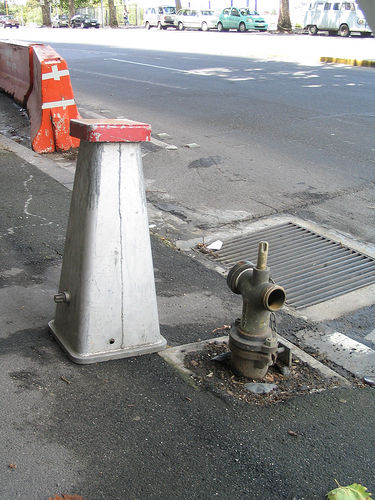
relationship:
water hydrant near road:
[226, 234, 294, 382] [2, 24, 375, 350]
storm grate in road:
[197, 222, 374, 307] [2, 24, 375, 350]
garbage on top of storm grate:
[198, 235, 229, 257] [197, 222, 374, 307]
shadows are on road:
[188, 57, 365, 93] [2, 24, 375, 350]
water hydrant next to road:
[226, 234, 294, 382] [2, 24, 375, 350]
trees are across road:
[32, 1, 124, 28] [2, 24, 375, 350]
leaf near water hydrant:
[327, 475, 371, 500] [226, 234, 294, 382]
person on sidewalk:
[123, 5, 132, 28] [98, 22, 306, 35]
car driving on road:
[2, 16, 24, 30] [2, 24, 375, 350]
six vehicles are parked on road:
[51, 3, 375, 35] [2, 24, 375, 350]